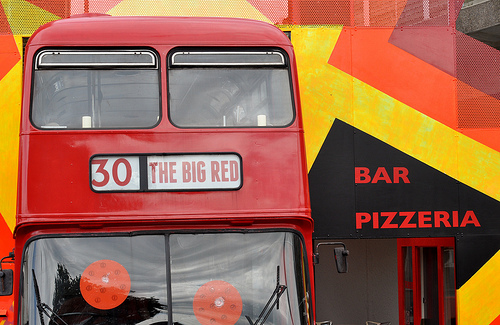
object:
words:
[147, 161, 184, 185]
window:
[42, 52, 158, 64]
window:
[169, 52, 295, 68]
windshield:
[167, 229, 312, 325]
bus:
[1, 11, 357, 325]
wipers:
[28, 267, 68, 325]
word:
[354, 166, 413, 186]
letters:
[350, 165, 374, 187]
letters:
[355, 212, 372, 230]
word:
[353, 207, 480, 232]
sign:
[89, 149, 247, 193]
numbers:
[87, 159, 109, 188]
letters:
[147, 162, 160, 184]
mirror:
[331, 246, 347, 275]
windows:
[15, 232, 171, 325]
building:
[0, 0, 500, 325]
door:
[400, 239, 456, 325]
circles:
[78, 256, 135, 312]